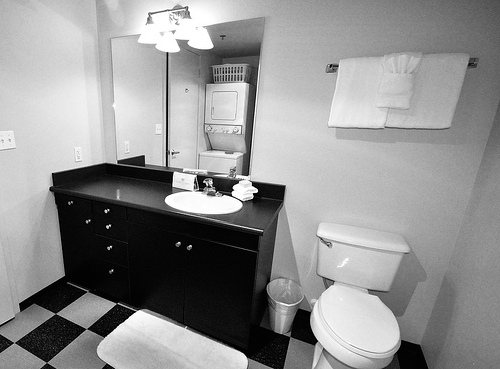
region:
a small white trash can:
[267, 275, 304, 337]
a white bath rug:
[92, 305, 247, 367]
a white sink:
[165, 190, 246, 216]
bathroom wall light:
[134, 9, 209, 43]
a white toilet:
[305, 219, 412, 367]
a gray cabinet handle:
[185, 242, 195, 250]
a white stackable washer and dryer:
[199, 82, 249, 173]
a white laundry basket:
[210, 63, 250, 79]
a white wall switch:
[0, 130, 15, 153]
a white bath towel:
[327, 55, 390, 130]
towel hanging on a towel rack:
[335, 55, 479, 133]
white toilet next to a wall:
[312, 210, 412, 365]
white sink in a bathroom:
[185, 168, 246, 225]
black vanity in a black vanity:
[65, 178, 155, 276]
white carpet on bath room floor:
[107, 307, 240, 367]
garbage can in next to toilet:
[259, 267, 307, 326]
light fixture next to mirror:
[138, 9, 220, 61]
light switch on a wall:
[2, 125, 24, 159]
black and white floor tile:
[32, 290, 102, 344]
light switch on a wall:
[62, 136, 90, 162]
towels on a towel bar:
[329, 45, 469, 148]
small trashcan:
[267, 267, 303, 342]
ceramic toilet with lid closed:
[299, 214, 431, 366]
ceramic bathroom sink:
[166, 180, 234, 223]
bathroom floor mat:
[85, 292, 271, 367]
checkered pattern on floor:
[0, 282, 142, 367]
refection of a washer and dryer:
[190, 78, 248, 177]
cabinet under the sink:
[132, 221, 259, 341]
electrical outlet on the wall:
[62, 142, 89, 169]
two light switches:
[0, 122, 41, 176]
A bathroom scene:
[14, 8, 484, 354]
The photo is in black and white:
[8, 7, 480, 358]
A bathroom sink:
[163, 170, 263, 231]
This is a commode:
[306, 220, 420, 367]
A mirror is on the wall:
[103, 28, 273, 170]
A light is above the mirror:
[134, 2, 217, 59]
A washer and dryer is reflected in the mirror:
[196, 76, 253, 171]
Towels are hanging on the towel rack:
[320, 45, 487, 145]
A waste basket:
[262, 272, 308, 344]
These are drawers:
[48, 190, 137, 302]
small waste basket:
[263, 262, 307, 346]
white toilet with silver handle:
[305, 210, 412, 365]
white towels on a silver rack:
[318, 41, 483, 148]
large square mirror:
[101, 12, 270, 179]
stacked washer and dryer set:
[200, 51, 257, 169]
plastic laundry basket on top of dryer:
[200, 56, 255, 101]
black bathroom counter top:
[48, 160, 287, 240]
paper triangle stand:
[157, 169, 207, 191]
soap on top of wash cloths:
[226, 172, 263, 210]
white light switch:
[1, 127, 18, 152]